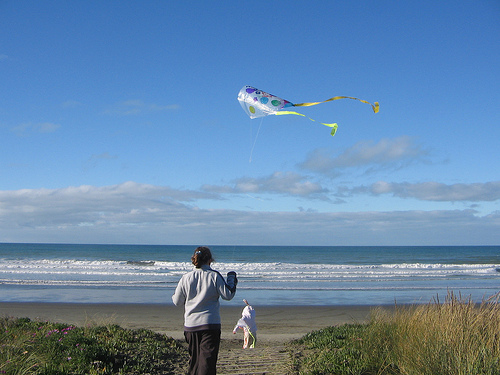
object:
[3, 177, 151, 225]
clouds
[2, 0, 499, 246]
horizon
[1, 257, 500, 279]
cap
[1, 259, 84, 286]
wave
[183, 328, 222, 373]
pants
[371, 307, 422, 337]
shrubs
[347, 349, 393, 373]
grass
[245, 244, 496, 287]
ocean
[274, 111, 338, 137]
tail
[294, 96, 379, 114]
tail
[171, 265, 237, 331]
jacket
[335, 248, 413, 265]
water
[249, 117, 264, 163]
string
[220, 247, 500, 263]
blue water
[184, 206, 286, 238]
clouds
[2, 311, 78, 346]
grass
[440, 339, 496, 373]
grass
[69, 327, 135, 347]
shrub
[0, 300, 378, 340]
beach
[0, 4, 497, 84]
blue sky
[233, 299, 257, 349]
white dog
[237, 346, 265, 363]
sand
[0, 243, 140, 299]
ocean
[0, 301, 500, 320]
wet sand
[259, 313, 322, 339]
shore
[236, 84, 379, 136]
kite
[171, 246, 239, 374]
woman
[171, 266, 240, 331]
shirt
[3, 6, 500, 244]
sky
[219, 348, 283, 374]
pathway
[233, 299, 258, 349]
person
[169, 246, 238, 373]
person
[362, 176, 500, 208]
clouds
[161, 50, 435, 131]
air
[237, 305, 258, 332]
cloths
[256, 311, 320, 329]
dunes